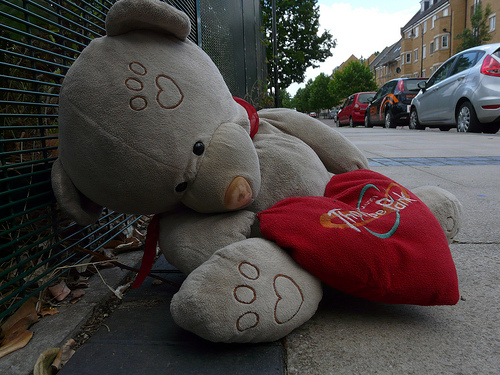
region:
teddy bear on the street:
[27, 1, 474, 361]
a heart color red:
[242, 151, 476, 329]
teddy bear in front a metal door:
[2, 0, 470, 372]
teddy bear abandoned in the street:
[28, 0, 492, 355]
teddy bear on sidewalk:
[40, 0, 471, 357]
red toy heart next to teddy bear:
[251, 163, 463, 330]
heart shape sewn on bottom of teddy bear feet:
[268, 267, 307, 328]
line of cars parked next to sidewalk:
[331, 39, 498, 133]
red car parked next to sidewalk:
[328, 88, 380, 130]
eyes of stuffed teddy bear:
[169, 130, 209, 199]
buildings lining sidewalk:
[328, 0, 499, 89]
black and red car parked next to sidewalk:
[360, 70, 432, 130]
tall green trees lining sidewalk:
[275, 48, 382, 120]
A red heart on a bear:
[255, 163, 461, 307]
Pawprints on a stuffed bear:
[229, 260, 302, 327]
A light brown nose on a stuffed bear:
[225, 178, 249, 208]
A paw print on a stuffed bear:
[122, 60, 184, 112]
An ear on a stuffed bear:
[102, 0, 194, 35]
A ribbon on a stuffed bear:
[125, 216, 156, 289]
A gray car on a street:
[409, 36, 499, 129]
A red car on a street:
[333, 88, 367, 127]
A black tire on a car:
[454, 102, 476, 133]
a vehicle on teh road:
[378, 69, 408, 129]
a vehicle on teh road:
[341, 88, 386, 151]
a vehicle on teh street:
[421, 45, 498, 130]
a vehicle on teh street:
[334, 86, 356, 119]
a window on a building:
[487, 9, 492, 36]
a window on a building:
[443, 35, 451, 55]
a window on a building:
[419, 18, 435, 38]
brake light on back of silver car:
[475, 51, 499, 83]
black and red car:
[358, 75, 431, 132]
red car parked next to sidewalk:
[333, 88, 378, 132]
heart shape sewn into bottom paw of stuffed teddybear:
[251, 161, 470, 318]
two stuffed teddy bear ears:
[43, 0, 196, 230]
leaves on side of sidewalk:
[1, 222, 140, 374]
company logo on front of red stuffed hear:
[316, 172, 420, 252]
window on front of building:
[437, 29, 452, 54]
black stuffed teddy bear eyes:
[171, 128, 202, 206]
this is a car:
[419, 45, 494, 130]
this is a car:
[368, 66, 410, 124]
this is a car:
[340, 83, 378, 125]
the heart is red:
[256, 168, 460, 304]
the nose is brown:
[223, 174, 253, 211]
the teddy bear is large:
[52, 0, 464, 342]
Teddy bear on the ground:
[21, 4, 490, 349]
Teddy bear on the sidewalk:
[30, 1, 483, 353]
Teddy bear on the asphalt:
[28, 8, 480, 356]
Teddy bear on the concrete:
[33, 3, 476, 363]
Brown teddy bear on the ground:
[27, 5, 480, 345]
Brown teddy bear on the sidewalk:
[38, 3, 481, 362]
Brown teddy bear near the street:
[35, 5, 479, 333]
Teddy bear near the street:
[38, 5, 490, 352]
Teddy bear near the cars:
[36, 5, 475, 344]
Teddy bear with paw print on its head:
[37, 5, 478, 354]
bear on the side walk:
[30, 6, 480, 368]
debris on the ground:
[0, 226, 165, 371]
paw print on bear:
[116, 55, 193, 127]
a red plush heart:
[254, 153, 480, 324]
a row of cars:
[303, 36, 498, 154]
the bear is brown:
[55, 0, 476, 361]